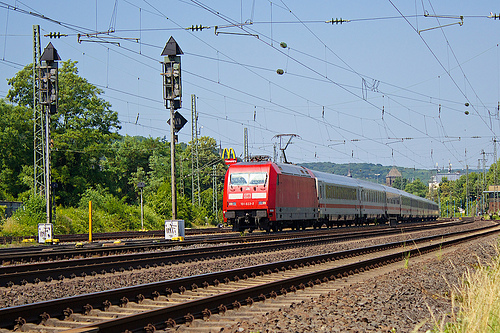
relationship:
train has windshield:
[224, 161, 442, 231] [229, 172, 267, 186]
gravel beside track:
[354, 287, 420, 320] [238, 250, 347, 294]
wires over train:
[246, 78, 414, 165] [224, 161, 442, 231]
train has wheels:
[224, 161, 442, 231] [259, 222, 335, 232]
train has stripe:
[224, 161, 442, 231] [322, 201, 410, 216]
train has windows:
[224, 161, 442, 231] [324, 184, 362, 201]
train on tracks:
[224, 161, 442, 231] [238, 244, 392, 284]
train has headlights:
[224, 161, 442, 231] [224, 198, 271, 209]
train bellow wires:
[224, 161, 442, 231] [246, 78, 414, 165]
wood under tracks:
[244, 303, 281, 315] [238, 244, 392, 284]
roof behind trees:
[428, 171, 464, 186] [444, 184, 468, 206]